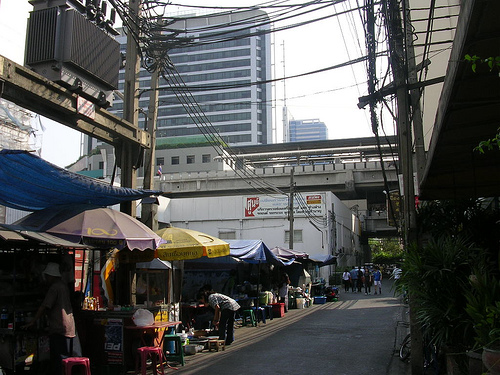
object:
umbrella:
[152, 224, 229, 262]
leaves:
[394, 274, 419, 289]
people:
[342, 268, 351, 294]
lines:
[146, 1, 386, 51]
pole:
[119, 0, 144, 216]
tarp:
[184, 238, 294, 267]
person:
[203, 290, 241, 346]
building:
[106, 180, 366, 293]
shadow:
[182, 298, 406, 375]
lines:
[179, 294, 361, 374]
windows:
[219, 232, 234, 239]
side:
[172, 192, 327, 300]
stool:
[137, 346, 165, 375]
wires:
[135, 49, 395, 97]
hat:
[42, 262, 62, 278]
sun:
[59, 304, 80, 337]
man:
[33, 261, 87, 363]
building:
[84, 8, 283, 169]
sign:
[242, 193, 326, 220]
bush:
[390, 140, 497, 373]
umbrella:
[9, 201, 165, 290]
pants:
[344, 280, 349, 291]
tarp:
[306, 253, 338, 268]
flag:
[157, 165, 162, 176]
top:
[153, 190, 338, 196]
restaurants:
[0, 200, 83, 375]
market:
[6, 157, 327, 374]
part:
[3, 305, 53, 342]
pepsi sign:
[8, 323, 14, 329]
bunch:
[393, 146, 500, 374]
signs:
[100, 316, 122, 361]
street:
[183, 292, 404, 374]